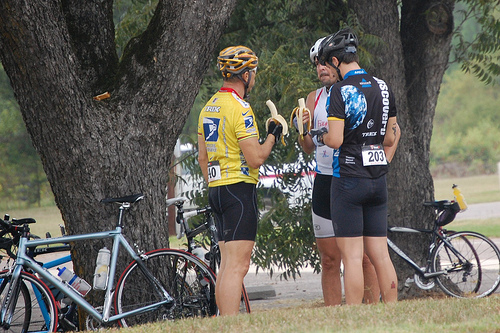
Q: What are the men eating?
A: Bananas.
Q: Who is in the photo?
A: Men.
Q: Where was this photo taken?
A: Outside on the grass.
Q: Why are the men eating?
A: They are hungry.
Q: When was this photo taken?
A: During the day.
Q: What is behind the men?
A: Trees.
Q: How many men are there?
A: Three.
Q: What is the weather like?
A: Sunny.